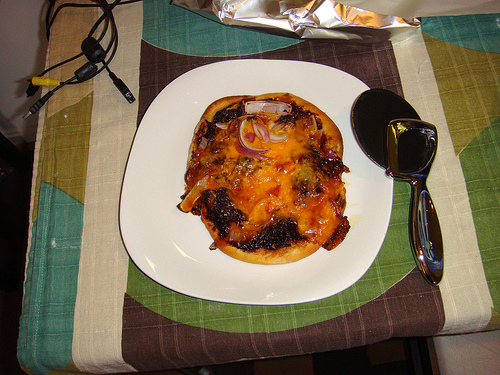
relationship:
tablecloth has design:
[61, 64, 499, 373] [43, 166, 133, 313]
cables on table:
[20, 3, 144, 110] [53, 11, 497, 239]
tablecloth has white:
[61, 64, 499, 373] [93, 100, 109, 224]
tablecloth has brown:
[61, 64, 499, 373] [135, 27, 175, 92]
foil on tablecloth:
[233, 5, 418, 43] [61, 64, 499, 373]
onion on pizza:
[235, 114, 271, 161] [206, 104, 368, 268]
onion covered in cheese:
[235, 114, 271, 161] [230, 142, 287, 219]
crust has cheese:
[291, 203, 348, 259] [230, 142, 287, 219]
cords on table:
[32, 20, 124, 73] [53, 11, 497, 239]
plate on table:
[115, 57, 396, 318] [53, 11, 497, 239]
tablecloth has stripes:
[61, 64, 499, 373] [150, 23, 484, 89]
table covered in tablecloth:
[53, 11, 497, 239] [61, 64, 499, 373]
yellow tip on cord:
[20, 29, 95, 134] [31, 79, 64, 89]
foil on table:
[233, 5, 418, 43] [53, 11, 497, 239]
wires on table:
[20, 3, 144, 110] [53, 11, 497, 239]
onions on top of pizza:
[219, 104, 306, 185] [206, 104, 368, 268]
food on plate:
[206, 104, 368, 268] [115, 57, 396, 318]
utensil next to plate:
[349, 83, 452, 288] [115, 57, 396, 318]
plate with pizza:
[115, 57, 396, 318] [206, 104, 368, 268]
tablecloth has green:
[61, 64, 499, 373] [238, 232, 401, 337]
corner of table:
[11, 289, 86, 372] [53, 11, 497, 239]